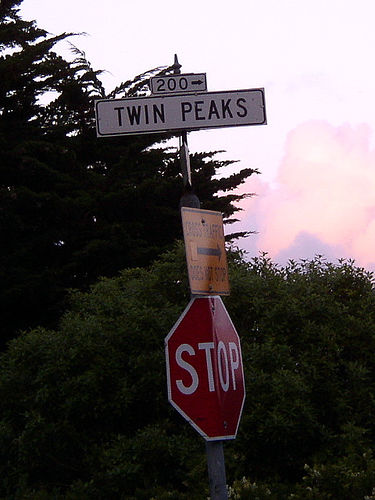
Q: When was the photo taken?
A: Day time.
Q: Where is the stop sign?
A: The pole.